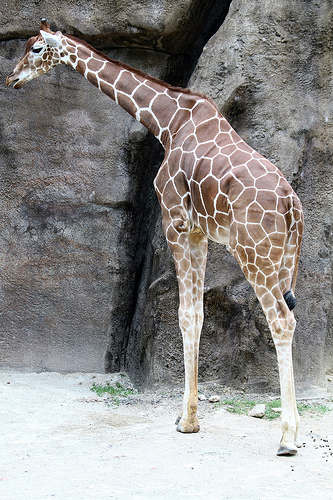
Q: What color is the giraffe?
A: Brown and white.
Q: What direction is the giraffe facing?
A: Left.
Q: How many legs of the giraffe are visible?
A: 2.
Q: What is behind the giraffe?
A: Stone boulders.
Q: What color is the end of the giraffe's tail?
A: Black.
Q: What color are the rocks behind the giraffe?
A: Grey.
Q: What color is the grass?
A: Green.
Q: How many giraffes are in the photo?
A: 1.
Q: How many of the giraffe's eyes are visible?
A: 1.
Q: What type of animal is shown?
A: Giraffe.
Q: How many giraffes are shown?
A: 1.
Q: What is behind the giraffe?
A: Rocks.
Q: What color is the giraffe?
A: Brown and tan.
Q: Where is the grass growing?
A: Base of the rock.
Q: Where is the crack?
A: In the rocks.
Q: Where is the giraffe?
A: At the zoo.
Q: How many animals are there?
A: One.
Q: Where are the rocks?
A: Behind the giraffe.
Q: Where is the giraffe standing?
A: In the dirt.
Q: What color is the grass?
A: Green.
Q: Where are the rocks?
A: On the ground.